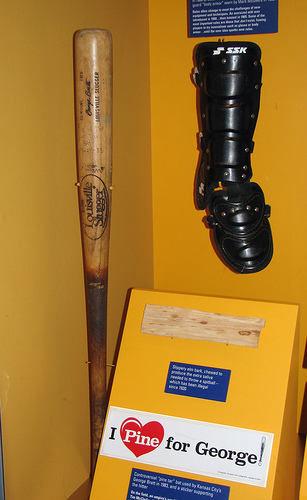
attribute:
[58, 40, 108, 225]
bat — wooden, slugger, leaning, dirty, displayed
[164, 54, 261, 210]
brace — safety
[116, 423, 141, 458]
letter — p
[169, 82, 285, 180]
shin — guard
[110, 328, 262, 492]
display — explaining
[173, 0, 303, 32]
sign — blue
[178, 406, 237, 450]
background — white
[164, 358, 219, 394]
lettering — white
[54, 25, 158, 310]
specimen — wooden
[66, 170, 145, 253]
slugger — printed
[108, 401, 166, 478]
heart — red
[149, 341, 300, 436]
label — blue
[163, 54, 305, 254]
padding — black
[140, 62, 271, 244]
wall — bright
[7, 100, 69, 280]
wall — brown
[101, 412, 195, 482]
shape — heart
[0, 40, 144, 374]
wood — displayed